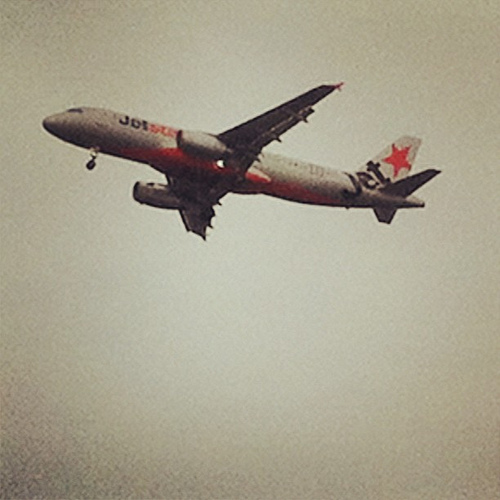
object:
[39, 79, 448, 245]
plane flying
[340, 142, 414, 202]
emblem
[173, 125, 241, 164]
engine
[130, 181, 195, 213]
engine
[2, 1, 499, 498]
sky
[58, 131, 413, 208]
plane's underside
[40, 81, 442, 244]
plane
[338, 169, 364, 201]
letters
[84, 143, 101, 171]
landing gear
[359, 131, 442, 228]
plane tail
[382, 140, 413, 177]
star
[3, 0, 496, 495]
no clouds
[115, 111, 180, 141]
name